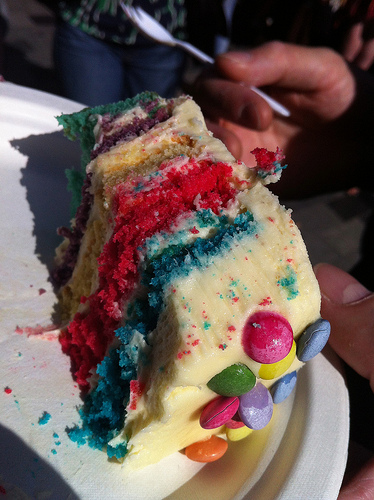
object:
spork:
[124, 5, 292, 120]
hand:
[202, 42, 366, 187]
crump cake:
[48, 428, 85, 460]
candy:
[252, 321, 292, 361]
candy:
[208, 366, 254, 398]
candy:
[295, 319, 332, 362]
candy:
[273, 373, 295, 403]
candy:
[240, 383, 274, 429]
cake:
[45, 90, 330, 468]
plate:
[0, 78, 351, 499]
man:
[203, 0, 374, 498]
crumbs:
[30, 408, 88, 456]